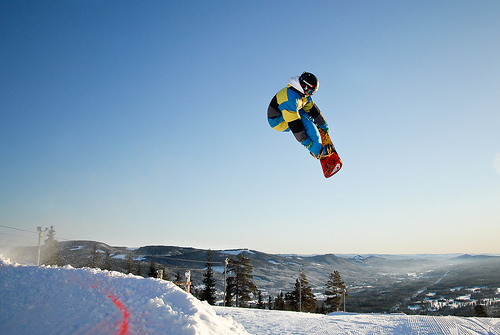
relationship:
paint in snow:
[83, 277, 133, 332] [0, 252, 495, 332]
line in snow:
[84, 279, 137, 331] [0, 252, 495, 332]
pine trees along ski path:
[279, 273, 366, 311] [360, 286, 442, 333]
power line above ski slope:
[7, 221, 58, 253] [17, 256, 204, 328]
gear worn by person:
[260, 82, 320, 136] [259, 67, 339, 169]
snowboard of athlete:
[319, 149, 341, 180] [278, 66, 330, 126]